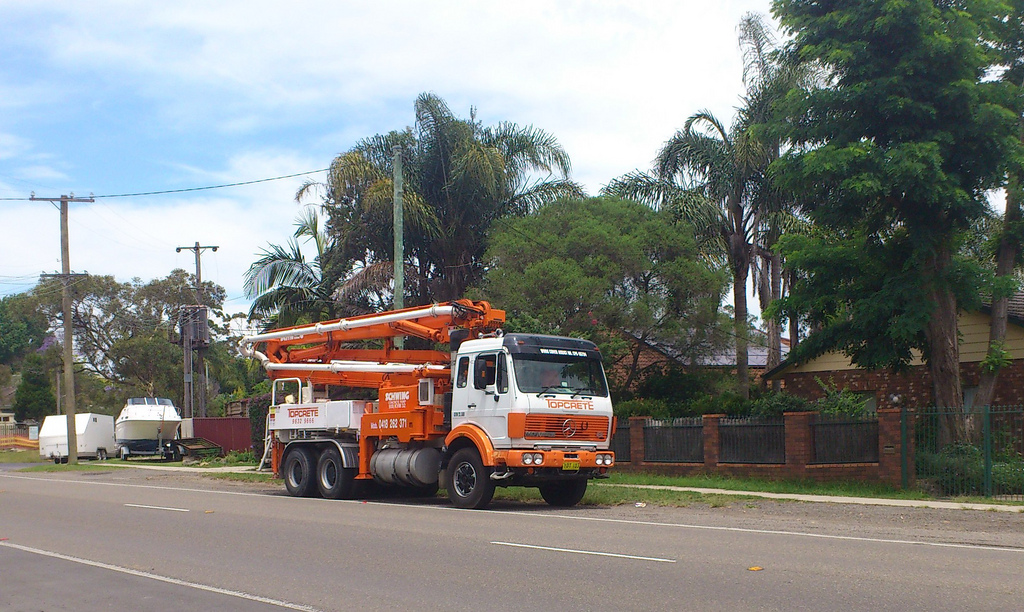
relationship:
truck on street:
[238, 290, 621, 521] [2, 448, 1023, 612]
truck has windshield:
[238, 290, 621, 521] [506, 349, 609, 397]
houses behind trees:
[586, 290, 1017, 495] [265, 8, 1023, 495]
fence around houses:
[586, 405, 929, 490] [586, 290, 1017, 495]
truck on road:
[238, 290, 621, 521] [2, 448, 1023, 612]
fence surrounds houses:
[586, 405, 929, 490] [759, 278, 1022, 480]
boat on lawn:
[106, 394, 189, 455] [5, 437, 245, 478]